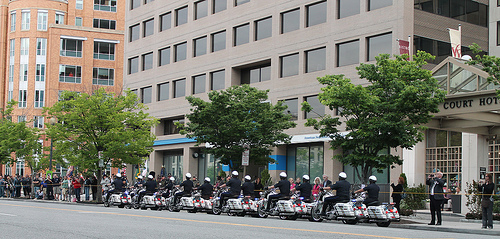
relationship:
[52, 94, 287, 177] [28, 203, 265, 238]
trees on street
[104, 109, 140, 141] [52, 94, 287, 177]
leaves on trees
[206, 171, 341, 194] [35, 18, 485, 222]
police officers in picture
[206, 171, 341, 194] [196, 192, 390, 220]
police officers riding motorcycles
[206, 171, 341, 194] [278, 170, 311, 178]
police officers wearing helmets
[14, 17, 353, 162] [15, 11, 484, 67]
buildings in background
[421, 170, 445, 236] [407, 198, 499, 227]
man on sidewalk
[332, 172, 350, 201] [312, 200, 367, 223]
man on motorcycle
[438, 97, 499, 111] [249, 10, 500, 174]
letters on building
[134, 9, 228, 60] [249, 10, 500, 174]
windows on building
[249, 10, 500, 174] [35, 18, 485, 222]
building in picture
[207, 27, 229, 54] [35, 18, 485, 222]
window in picture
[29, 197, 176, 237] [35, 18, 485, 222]
road in picture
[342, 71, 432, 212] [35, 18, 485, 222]
tree in picture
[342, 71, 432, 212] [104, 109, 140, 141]
tree has leaves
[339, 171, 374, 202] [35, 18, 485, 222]
motorists in picture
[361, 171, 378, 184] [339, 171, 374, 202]
helmet on motorists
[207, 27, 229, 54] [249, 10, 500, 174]
window on building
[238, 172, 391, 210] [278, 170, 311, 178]
people wearing helmets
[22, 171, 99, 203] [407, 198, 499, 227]
people on sidewalk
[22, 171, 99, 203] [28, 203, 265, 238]
people on street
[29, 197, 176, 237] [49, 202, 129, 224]
road has lines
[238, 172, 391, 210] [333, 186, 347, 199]
people wearing black